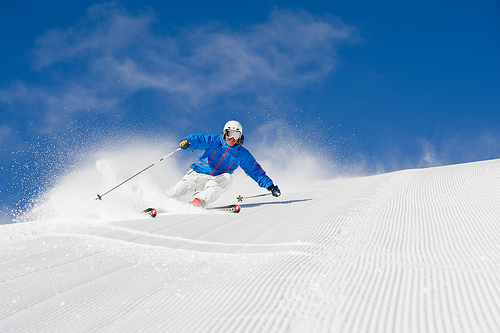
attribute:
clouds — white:
[2, 0, 360, 162]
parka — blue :
[177, 133, 290, 193]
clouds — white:
[15, 11, 343, 133]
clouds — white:
[113, 33, 286, 75]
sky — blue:
[12, 42, 149, 128]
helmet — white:
[224, 120, 244, 135]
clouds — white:
[262, 24, 341, 75]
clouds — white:
[31, 10, 341, 155]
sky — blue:
[258, 29, 363, 91]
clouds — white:
[154, 41, 269, 108]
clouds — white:
[45, 20, 360, 110]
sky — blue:
[1, 0, 498, 171]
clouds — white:
[94, 38, 275, 98]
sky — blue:
[380, 30, 466, 95]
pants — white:
[153, 172, 234, 205]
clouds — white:
[100, 33, 362, 92]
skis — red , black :
[135, 196, 249, 221]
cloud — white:
[242, 9, 359, 89]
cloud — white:
[105, 24, 245, 97]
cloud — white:
[7, 73, 120, 145]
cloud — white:
[23, 10, 149, 62]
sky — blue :
[364, 70, 459, 122]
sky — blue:
[8, 8, 496, 118]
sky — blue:
[2, 2, 497, 227]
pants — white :
[84, 139, 306, 222]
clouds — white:
[244, 11, 331, 88]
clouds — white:
[38, 28, 118, 107]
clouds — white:
[4, 12, 405, 112]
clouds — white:
[85, 14, 335, 97]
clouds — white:
[63, 17, 349, 113]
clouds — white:
[103, 9, 348, 103]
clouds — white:
[84, 33, 307, 92]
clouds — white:
[94, 33, 296, 100]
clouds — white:
[69, 37, 286, 102]